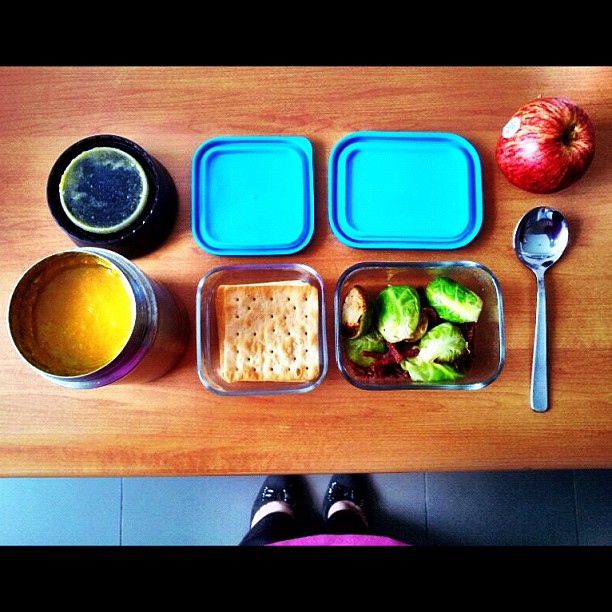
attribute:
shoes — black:
[254, 475, 365, 506]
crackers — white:
[223, 293, 300, 367]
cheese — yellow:
[51, 291, 97, 336]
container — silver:
[3, 244, 188, 390]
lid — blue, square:
[187, 131, 319, 260]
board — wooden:
[9, 86, 609, 448]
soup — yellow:
[21, 255, 133, 374]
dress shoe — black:
[319, 474, 360, 524]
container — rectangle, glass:
[332, 258, 506, 393]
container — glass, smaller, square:
[191, 260, 331, 400]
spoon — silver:
[510, 203, 571, 412]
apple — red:
[491, 90, 592, 194]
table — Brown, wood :
[4, 62, 591, 465]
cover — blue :
[186, 136, 311, 263]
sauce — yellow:
[52, 298, 92, 336]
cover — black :
[42, 131, 168, 251]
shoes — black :
[244, 480, 369, 513]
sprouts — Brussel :
[363, 287, 473, 373]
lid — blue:
[187, 131, 488, 253]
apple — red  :
[495, 95, 592, 182]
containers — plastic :
[190, 260, 517, 397]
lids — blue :
[191, 122, 489, 248]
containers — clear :
[181, 255, 523, 404]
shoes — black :
[245, 469, 375, 525]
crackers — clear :
[224, 287, 313, 372]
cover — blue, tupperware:
[192, 127, 323, 263]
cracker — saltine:
[211, 277, 326, 387]